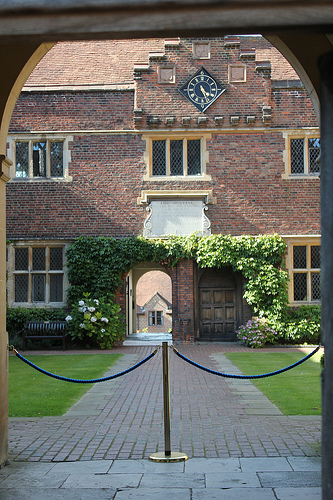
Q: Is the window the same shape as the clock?
A: Yes, both the window and the clock are square.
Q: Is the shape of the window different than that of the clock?
A: No, both the window and the clock are square.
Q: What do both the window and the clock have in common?
A: The shape, both the window and the clock are square.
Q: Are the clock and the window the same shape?
A: Yes, both the clock and the window are square.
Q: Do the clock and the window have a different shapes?
A: No, both the clock and the window are square.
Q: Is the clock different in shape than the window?
A: No, both the clock and the window are square.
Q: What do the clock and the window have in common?
A: The shape, both the clock and the window are square.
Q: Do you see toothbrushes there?
A: No, there are no toothbrushes.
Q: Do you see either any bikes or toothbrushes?
A: No, there are no toothbrushes or bikes.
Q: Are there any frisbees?
A: No, there are no frisbees.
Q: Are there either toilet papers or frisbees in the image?
A: No, there are no frisbees or toilet papers.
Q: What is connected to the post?
A: The rope is connected to the post.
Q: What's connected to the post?
A: The rope is connected to the post.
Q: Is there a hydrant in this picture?
A: No, there are no fire hydrants.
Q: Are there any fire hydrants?
A: No, there are no fire hydrants.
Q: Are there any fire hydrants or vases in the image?
A: No, there are no fire hydrants or vases.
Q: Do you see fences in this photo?
A: No, there are no fences.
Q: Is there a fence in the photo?
A: No, there are no fences.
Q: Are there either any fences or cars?
A: No, there are no fences or cars.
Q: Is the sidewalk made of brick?
A: Yes, the sidewalk is made of brick.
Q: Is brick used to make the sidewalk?
A: Yes, the sidewalk is made of brick.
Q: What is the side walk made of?
A: The side walk is made of brick.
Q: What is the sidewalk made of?
A: The side walk is made of brick.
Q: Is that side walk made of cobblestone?
A: No, the side walk is made of brick.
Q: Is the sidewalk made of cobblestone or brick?
A: The sidewalk is made of brick.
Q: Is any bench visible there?
A: Yes, there is a bench.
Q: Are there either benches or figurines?
A: Yes, there is a bench.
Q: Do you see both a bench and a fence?
A: No, there is a bench but no fences.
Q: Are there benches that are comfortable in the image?
A: Yes, there is a comfortable bench.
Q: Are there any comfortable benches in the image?
A: Yes, there is a comfortable bench.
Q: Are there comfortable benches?
A: Yes, there is a comfortable bench.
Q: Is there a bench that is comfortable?
A: Yes, there is a bench that is comfortable.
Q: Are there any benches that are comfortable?
A: Yes, there is a bench that is comfortable.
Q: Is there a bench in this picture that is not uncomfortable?
A: Yes, there is an comfortable bench.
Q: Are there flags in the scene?
A: No, there are no flags.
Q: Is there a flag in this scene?
A: No, there are no flags.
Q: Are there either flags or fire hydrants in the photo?
A: No, there are no flags or fire hydrants.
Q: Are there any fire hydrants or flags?
A: No, there are no flags or fire hydrants.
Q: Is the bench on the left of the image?
A: Yes, the bench is on the left of the image.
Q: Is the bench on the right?
A: No, the bench is on the left of the image.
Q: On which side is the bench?
A: The bench is on the left of the image.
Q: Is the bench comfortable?
A: Yes, the bench is comfortable.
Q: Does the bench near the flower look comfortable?
A: Yes, the bench is comfortable.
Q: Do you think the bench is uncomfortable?
A: No, the bench is comfortable.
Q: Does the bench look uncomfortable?
A: No, the bench is comfortable.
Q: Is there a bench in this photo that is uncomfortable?
A: No, there is a bench but it is comfortable.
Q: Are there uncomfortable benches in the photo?
A: No, there is a bench but it is comfortable.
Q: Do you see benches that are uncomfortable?
A: No, there is a bench but it is comfortable.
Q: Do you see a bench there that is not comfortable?
A: No, there is a bench but it is comfortable.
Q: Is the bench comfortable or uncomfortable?
A: The bench is comfortable.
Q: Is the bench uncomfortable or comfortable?
A: The bench is comfortable.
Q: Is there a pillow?
A: No, there are no pillows.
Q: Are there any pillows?
A: No, there are no pillows.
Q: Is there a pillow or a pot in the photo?
A: No, there are no pillows or pots.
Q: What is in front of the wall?
A: The bush is in front of the wall.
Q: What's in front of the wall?
A: The bush is in front of the wall.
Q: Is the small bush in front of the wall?
A: Yes, the bush is in front of the wall.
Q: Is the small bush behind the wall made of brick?
A: No, the shrub is in front of the wall.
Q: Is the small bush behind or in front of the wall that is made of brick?
A: The shrub is in front of the wall.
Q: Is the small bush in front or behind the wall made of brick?
A: The shrub is in front of the wall.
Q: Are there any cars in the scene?
A: No, there are no cars.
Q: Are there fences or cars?
A: No, there are no cars or fences.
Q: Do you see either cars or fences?
A: No, there are no cars or fences.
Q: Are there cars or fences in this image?
A: No, there are no cars or fences.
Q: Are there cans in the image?
A: No, there are no cans.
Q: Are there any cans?
A: No, there are no cans.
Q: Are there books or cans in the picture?
A: No, there are no cans or books.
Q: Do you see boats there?
A: No, there are no boats.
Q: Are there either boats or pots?
A: No, there are no boats or pots.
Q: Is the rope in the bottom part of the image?
A: Yes, the rope is in the bottom of the image.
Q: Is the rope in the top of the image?
A: No, the rope is in the bottom of the image.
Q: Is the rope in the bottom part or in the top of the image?
A: The rope is in the bottom of the image.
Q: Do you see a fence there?
A: No, there are no fences.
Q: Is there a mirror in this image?
A: No, there are no mirrors.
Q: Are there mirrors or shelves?
A: No, there are no mirrors or shelves.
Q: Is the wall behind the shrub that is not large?
A: Yes, the wall is behind the shrub.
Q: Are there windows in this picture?
A: Yes, there is a window.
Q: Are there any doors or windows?
A: Yes, there is a window.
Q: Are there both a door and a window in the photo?
A: Yes, there are both a window and a door.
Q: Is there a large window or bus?
A: Yes, there is a large window.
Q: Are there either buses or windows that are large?
A: Yes, the window is large.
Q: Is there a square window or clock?
A: Yes, there is a square window.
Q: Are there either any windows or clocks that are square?
A: Yes, the window is square.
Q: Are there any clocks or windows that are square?
A: Yes, the window is square.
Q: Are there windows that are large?
A: Yes, there is a large window.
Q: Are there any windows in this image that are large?
A: Yes, there is a window that is large.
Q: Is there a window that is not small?
A: Yes, there is a large window.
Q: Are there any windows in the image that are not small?
A: Yes, there is a large window.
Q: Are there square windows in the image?
A: Yes, there is a square window.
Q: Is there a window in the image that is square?
A: Yes, there is a window that is square.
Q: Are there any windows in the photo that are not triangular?
A: Yes, there is a square window.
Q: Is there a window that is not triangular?
A: Yes, there is a square window.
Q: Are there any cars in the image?
A: No, there are no cars.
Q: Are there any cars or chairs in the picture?
A: No, there are no cars or chairs.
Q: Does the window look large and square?
A: Yes, the window is large and square.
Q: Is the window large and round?
A: No, the window is large but square.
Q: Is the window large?
A: Yes, the window is large.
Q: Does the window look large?
A: Yes, the window is large.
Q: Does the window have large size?
A: Yes, the window is large.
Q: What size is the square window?
A: The window is large.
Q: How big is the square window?
A: The window is large.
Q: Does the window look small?
A: No, the window is large.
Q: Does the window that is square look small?
A: No, the window is large.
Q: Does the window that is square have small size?
A: No, the window is large.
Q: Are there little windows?
A: No, there is a window but it is large.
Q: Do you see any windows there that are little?
A: No, there is a window but it is large.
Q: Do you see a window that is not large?
A: No, there is a window but it is large.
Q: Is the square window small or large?
A: The window is large.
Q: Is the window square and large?
A: Yes, the window is square and large.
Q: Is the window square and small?
A: No, the window is square but large.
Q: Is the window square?
A: Yes, the window is square.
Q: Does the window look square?
A: Yes, the window is square.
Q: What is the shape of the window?
A: The window is square.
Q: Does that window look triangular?
A: No, the window is square.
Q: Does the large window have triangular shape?
A: No, the window is square.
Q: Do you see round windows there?
A: No, there is a window but it is square.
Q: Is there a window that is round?
A: No, there is a window but it is square.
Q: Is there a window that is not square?
A: No, there is a window but it is square.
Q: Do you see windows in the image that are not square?
A: No, there is a window but it is square.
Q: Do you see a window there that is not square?
A: No, there is a window but it is square.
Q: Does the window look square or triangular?
A: The window is square.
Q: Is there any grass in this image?
A: Yes, there is grass.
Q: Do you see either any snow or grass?
A: Yes, there is grass.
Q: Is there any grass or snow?
A: Yes, there is grass.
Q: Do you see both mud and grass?
A: No, there is grass but no mud.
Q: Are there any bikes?
A: No, there are no bikes.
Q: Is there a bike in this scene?
A: No, there are no bikes.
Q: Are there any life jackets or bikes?
A: No, there are no bikes or life jackets.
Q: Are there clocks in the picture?
A: Yes, there is a clock.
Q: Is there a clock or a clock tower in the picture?
A: Yes, there is a clock.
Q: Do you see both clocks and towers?
A: No, there is a clock but no towers.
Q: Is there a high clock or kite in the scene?
A: Yes, there is a high clock.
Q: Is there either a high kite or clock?
A: Yes, there is a high clock.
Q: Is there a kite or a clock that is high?
A: Yes, the clock is high.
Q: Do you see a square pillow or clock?
A: Yes, there is a square clock.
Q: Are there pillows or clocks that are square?
A: Yes, the clock is square.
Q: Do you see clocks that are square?
A: Yes, there is a square clock.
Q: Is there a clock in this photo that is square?
A: Yes, there is a clock that is square.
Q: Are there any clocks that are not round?
A: Yes, there is a square clock.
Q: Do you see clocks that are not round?
A: Yes, there is a square clock.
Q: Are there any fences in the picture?
A: No, there are no fences.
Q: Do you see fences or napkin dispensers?
A: No, there are no fences or napkin dispensers.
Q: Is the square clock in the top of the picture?
A: Yes, the clock is in the top of the image.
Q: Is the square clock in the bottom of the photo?
A: No, the clock is in the top of the image.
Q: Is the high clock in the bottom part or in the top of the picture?
A: The clock is in the top of the image.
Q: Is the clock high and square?
A: Yes, the clock is high and square.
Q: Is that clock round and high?
A: No, the clock is high but square.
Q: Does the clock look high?
A: Yes, the clock is high.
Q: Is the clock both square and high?
A: Yes, the clock is square and high.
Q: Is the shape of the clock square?
A: Yes, the clock is square.